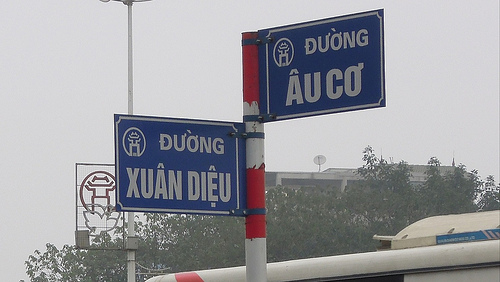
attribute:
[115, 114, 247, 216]
sign — for street, not illuminated, not neon, blue, strange, white, displayed, board, big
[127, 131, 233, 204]
writing — possibly vietnamese, foreign, white, text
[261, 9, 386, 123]
sign — for street, not illuminated, not neon, blue, strange, white, displayed, board, big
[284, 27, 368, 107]
writing — possibly vietnamese, foreign, white, text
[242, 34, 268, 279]
pole — striped, light, very tall, metal, red, white, colorful, one, surrounded by fog, long, on top of road, very long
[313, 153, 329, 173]
dish — for satellite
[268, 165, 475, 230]
building — concrete, in the background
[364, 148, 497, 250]
tree — in background, green, dark, part of group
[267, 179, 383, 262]
tree — in background, green, dark, part of group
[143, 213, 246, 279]
tree — in background, green, dark, part of group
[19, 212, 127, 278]
tree — in background, green, dark, part of group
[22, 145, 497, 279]
foliage — in background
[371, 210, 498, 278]
bus — a possibility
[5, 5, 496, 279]
skies — foggy, cloudless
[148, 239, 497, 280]
pipe — small, white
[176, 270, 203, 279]
mark — red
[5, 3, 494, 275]
view — beautiful